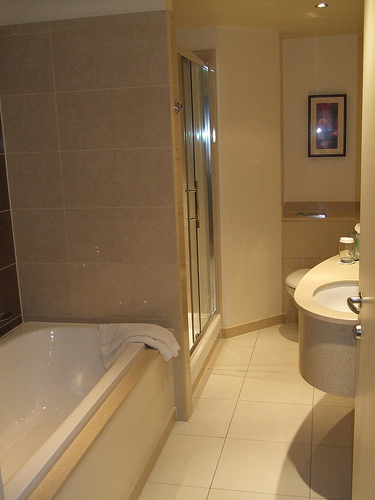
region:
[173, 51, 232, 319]
Bathroom glass shower door.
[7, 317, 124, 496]
Long deep white bathtub.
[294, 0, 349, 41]
Ceiling recessed lighting fixture.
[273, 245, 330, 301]
Toilet hidden behind sink.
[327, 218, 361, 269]
Glass jars on sink counter.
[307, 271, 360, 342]
Deep round sink basin.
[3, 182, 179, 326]
Tile back splash walls.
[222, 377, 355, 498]
Flooring large ceramic tiles.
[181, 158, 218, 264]
Show door slides open.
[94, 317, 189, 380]
White towels folded tub.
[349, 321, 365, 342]
lock on a door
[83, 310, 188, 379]
white towel on a bathtub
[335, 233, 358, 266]
glass on a sink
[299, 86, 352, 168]
picture on a wall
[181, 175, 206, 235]
handle on a shower door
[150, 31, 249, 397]
shower in a bathroom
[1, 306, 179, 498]
white bathtub in a bathroom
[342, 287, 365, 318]
handle on a door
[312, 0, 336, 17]
recessed light in a ceiling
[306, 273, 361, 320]
white sink in a bathroom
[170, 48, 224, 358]
A GLASS SHOWER DOOR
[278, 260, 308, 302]
A WHITE TOILET WITH THE SEAT DOWN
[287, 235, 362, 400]
A BATHROOM SINK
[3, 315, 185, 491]
A WHITE TOWEL ON A BATHTUB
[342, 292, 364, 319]
BATHROOM DOOR HANDLE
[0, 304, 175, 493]
A WHITE BATH TUB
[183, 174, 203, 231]
SHOWER DOOR HANDLE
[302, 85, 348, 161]
PICTURE ON A WALL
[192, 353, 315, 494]
WHITE BATHROOM FLOOR TILES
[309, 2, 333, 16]
OVERHEAD LIGHTING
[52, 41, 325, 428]
clean and modern bathroom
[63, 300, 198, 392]
bath mat draped over tub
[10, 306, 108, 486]
white porcelain surface of bathtub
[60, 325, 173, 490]
extra tan wall on bathtub exterior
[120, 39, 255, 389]
glass and silver shower doors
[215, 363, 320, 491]
tan square tiles on floor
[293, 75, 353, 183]
rectangular artwork on wall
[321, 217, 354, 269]
small glass cup with paper covering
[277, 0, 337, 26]
overhead lighting turned on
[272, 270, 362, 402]
curved surface below sink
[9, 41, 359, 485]
A picture of a bathroom.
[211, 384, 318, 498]
Tan tile floor.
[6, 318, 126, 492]
A white bathtub.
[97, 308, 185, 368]
A white towel draped over tub.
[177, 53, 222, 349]
A door to the shower stall.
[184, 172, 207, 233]
A handle on door to shower stall.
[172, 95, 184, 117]
A silver hook to hang things on.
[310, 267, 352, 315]
A white sink.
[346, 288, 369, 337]
A silver handle and lock on door.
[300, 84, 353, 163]
A picture with a dark frame.